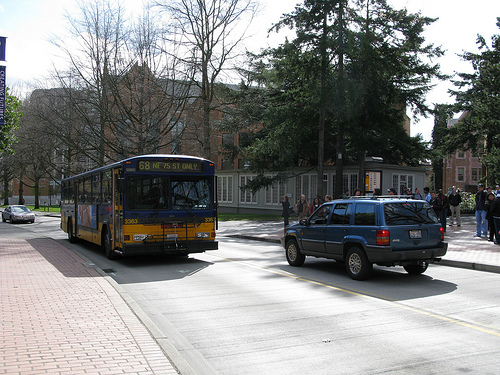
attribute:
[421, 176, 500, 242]
people — chatting, standing, talking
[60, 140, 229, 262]
bus — blurry, blue, gold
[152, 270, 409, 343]
road — clean, carpeted, pavements, good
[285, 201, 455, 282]
car — blue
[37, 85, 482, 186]
buildings — tall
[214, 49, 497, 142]
trees — green, tall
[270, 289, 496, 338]
markings — yellow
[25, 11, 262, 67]
weather — sunny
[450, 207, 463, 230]
trousers — beige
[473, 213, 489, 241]
jeans — blue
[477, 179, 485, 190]
cap — black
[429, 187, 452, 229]
guy — black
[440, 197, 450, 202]
shirt — red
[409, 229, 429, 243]
plates — white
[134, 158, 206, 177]
words — yellow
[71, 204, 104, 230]
sign — blue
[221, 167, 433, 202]
building — grey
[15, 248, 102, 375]
sidewalk — bricks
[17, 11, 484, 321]
picture — outdoor, daytime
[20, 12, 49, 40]
clouds — grey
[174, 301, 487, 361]
surface — paved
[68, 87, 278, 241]
asphalt — clean, dry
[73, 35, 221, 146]
tree — bare